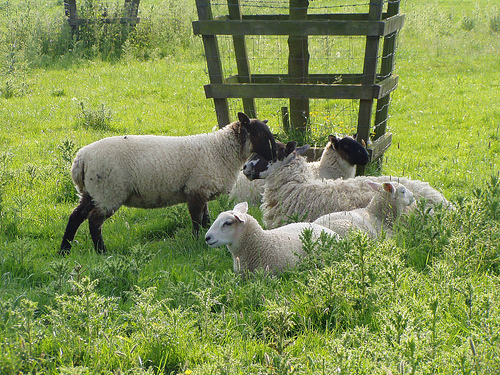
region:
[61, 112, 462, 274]
Group of sheep laying in grass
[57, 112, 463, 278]
Five sheep laying in grass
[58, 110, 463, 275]
Five sheep laying in tall grass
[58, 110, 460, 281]
Five sheep relaxing in grass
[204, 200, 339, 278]
White sheep laying in grass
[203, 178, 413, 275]
Two white faced sheep laying in grass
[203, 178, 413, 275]
Two white faced sheep in tall grass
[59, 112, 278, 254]
Sheep standing in grass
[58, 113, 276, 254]
Black faced sheep standing in grass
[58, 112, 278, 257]
Sheep with black face standing in grass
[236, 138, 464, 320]
sheep laying in the grass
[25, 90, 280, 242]
sheep standing in the grass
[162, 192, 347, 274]
the sheep is white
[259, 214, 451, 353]
the grass is tall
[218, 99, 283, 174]
the face is black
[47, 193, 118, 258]
the legs are black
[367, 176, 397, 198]
the inside of the ear is pink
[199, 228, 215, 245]
the nose is black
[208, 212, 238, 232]
the eye is black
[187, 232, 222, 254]
the mouth is closed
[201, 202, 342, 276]
The closest white sheep lying down.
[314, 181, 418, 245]
The smallest white sheep pointed right.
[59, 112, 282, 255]
Black and white sheep standing up to the left of the rest.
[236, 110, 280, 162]
Black head and ears of a standing sheep on the left.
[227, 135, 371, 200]
Black headed sheep furthest away lying down.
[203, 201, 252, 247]
White head of a the closest sheep.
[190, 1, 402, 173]
Several wooden boards and fencing around a tree trunk.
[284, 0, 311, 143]
A thin brown tree trunk behind the sheep.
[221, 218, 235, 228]
Black eye of the closest white sheep.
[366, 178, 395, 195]
White ears on the smallest sheep pointing right.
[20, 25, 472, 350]
The sheep are on a farm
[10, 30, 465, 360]
The sheep are in a field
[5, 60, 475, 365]
The sheep are very close together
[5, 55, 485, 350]
The sheep resting in a pasture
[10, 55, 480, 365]
The sheep are owned by a farmer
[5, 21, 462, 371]
The sheep are watching for danger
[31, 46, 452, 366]
The sheep are eating the grass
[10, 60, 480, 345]
The sheep are out in the sunshine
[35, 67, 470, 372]
The sheep are enjoying the day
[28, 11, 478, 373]
The sheep are among the tall weeds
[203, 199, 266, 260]
the sheep has a white face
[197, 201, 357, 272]
the sheep is laying down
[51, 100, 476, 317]
the sheep are in a field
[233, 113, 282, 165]
the sheep has a black face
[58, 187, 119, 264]
this sheeps back legs have black on them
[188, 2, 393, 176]
the wooden object is made of wood and wire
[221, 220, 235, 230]
his eyes are open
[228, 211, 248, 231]
this sheeps ears are flat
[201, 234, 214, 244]
this sheeps nose is black